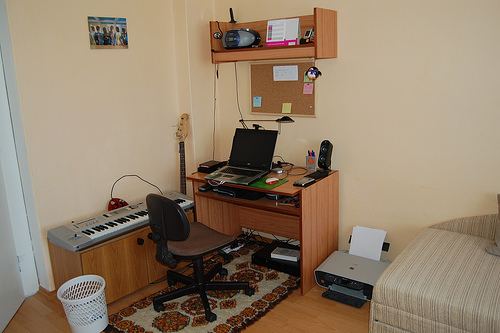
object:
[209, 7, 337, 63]
shelf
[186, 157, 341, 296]
desk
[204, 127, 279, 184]
laptop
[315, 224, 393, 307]
printer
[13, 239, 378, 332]
floor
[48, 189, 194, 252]
keyboard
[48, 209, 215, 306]
cabinet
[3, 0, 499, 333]
room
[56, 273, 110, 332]
trash can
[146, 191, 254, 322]
office chair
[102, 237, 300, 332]
rug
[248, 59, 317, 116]
corkboard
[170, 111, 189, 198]
guitar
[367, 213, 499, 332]
couch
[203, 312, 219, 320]
wheels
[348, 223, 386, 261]
paper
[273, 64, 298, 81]
notes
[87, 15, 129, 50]
poster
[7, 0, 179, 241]
wall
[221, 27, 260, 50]
boombox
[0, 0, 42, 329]
door